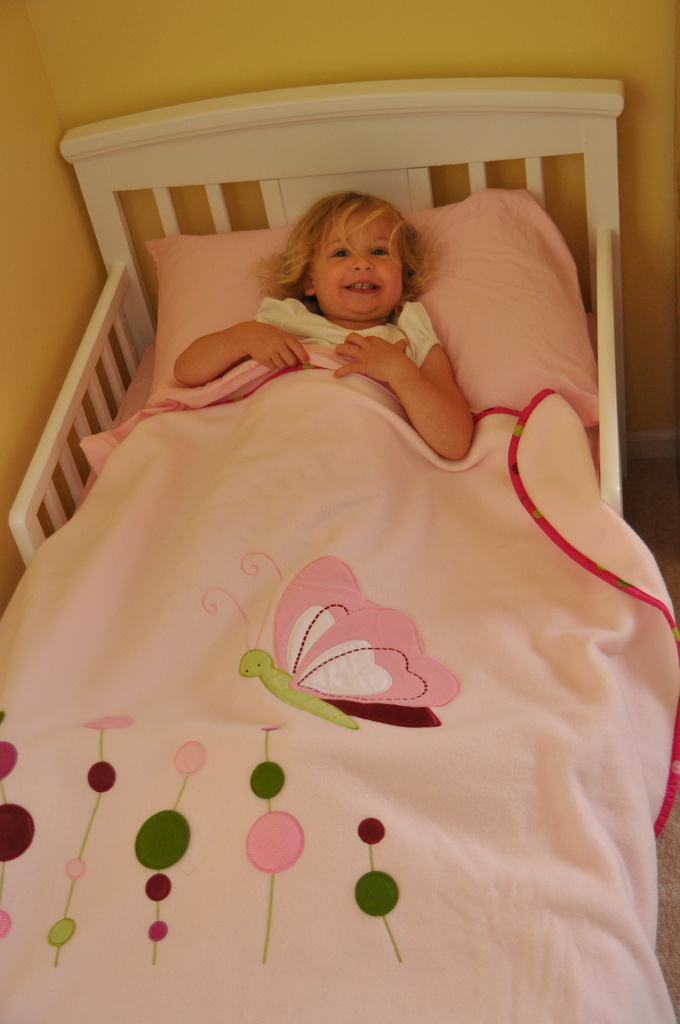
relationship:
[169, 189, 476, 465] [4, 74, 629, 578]
child tucked in bed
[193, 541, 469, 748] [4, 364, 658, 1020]
butterfly on blanket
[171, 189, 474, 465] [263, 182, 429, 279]
child has hair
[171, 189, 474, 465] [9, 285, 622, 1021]
child tucked in bed